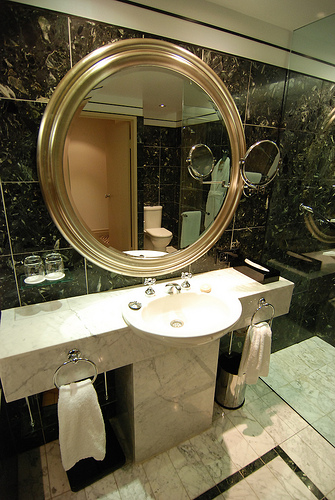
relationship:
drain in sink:
[168, 319, 182, 327] [121, 284, 241, 349]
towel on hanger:
[241, 325, 275, 384] [251, 297, 275, 328]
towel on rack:
[57, 384, 114, 471] [51, 358, 100, 387]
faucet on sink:
[160, 270, 189, 303] [130, 270, 233, 332]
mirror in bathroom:
[241, 136, 280, 190] [3, 10, 333, 499]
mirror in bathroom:
[30, 35, 246, 275] [3, 10, 333, 499]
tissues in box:
[241, 254, 272, 273] [238, 248, 278, 285]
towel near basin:
[57, 379, 106, 471] [122, 287, 243, 349]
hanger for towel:
[248, 300, 278, 327] [236, 323, 277, 388]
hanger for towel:
[50, 356, 107, 385] [53, 379, 115, 468]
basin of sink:
[124, 273, 244, 342] [119, 266, 244, 443]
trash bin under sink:
[216, 351, 248, 410] [0, 258, 294, 461]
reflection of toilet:
[78, 82, 223, 256] [137, 200, 172, 247]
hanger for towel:
[52, 348, 99, 390] [46, 379, 112, 472]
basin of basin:
[124, 273, 244, 342] [122, 287, 243, 349]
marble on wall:
[12, 18, 38, 56] [0, 1, 285, 297]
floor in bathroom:
[247, 387, 308, 441] [3, 10, 333, 499]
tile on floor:
[227, 426, 326, 497] [247, 387, 308, 441]